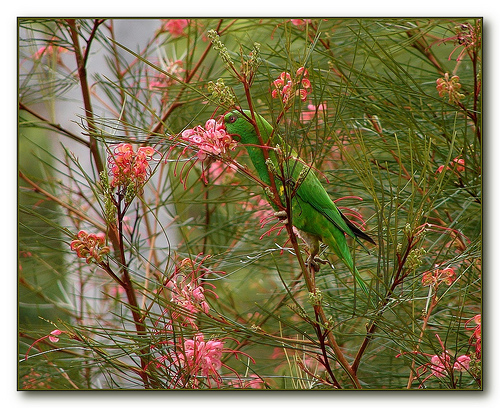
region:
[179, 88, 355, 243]
bird in the flowers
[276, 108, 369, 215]
green feathers on bird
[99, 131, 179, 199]
pink flower on tree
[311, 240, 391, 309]
tail feather of bird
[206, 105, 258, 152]
hed of the bird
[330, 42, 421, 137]
green part of the flowers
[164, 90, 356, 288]
bird with face in flowers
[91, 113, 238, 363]
many different pink flowers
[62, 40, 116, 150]
brown stick on tree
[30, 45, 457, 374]
many different branches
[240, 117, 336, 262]
this is a parrot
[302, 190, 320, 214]
the parrot is green in color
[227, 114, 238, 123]
the eye is red in color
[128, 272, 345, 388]
flowers are all over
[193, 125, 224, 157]
the flower is pink in color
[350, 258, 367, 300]
the tail is long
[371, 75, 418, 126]
the leaves are thin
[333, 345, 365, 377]
the stem is thin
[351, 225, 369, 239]
the feather has black strip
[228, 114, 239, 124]
the eye is open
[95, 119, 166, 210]
this flower is pink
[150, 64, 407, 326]
bird is eating flowers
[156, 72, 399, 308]
the bird is green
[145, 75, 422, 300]
the bird is a parrot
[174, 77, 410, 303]
the parrot has red eyes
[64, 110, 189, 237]
the flowers are curling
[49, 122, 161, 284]
two pink flowers in the box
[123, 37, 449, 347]
the tree is in bloom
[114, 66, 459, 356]
the bird is camouflaged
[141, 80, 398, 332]
the branches are red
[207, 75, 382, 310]
green bird sitting on branch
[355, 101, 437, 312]
thin and long needle-like leaves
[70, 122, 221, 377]
pink flowers growing on ends of twigs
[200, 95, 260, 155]
bird's head deep inside flower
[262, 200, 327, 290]
claws curled around different branches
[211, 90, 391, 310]
long bird with wings folded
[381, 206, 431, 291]
light green buds forming on twigs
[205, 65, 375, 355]
long branch extending in front of bird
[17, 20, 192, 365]
muted white object in back of branches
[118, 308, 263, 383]
long and slender red growths from center of flower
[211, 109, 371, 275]
this is a bird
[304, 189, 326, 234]
the feathers are green in color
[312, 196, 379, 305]
this is a tail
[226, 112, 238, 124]
this is an eye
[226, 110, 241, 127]
the eye is open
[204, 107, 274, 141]
this is the bird's eye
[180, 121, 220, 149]
this is a flower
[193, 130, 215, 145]
the flower is pink in color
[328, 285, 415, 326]
the leaves are green in color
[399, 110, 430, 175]
the leaves are thin